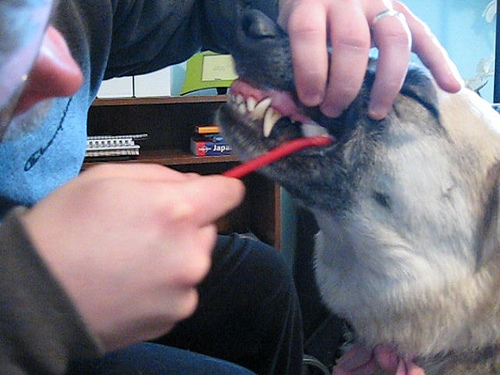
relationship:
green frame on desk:
[177, 48, 238, 100] [78, 85, 287, 262]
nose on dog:
[237, 6, 282, 41] [215, 6, 497, 373]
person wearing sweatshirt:
[1, 2, 463, 372] [0, 1, 275, 371]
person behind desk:
[1, 2, 465, 375] [77, 86, 292, 245]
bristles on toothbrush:
[301, 123, 327, 138] [217, 121, 330, 178]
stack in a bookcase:
[189, 124, 234, 154] [87, 94, 283, 252]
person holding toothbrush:
[1, 2, 465, 375] [210, 117, 339, 186]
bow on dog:
[333, 340, 425, 375] [206, 47, 496, 372]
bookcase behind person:
[81, 94, 283, 252] [1, 2, 463, 372]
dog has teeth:
[215, 6, 497, 373] [217, 88, 282, 140]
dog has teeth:
[215, 6, 499, 375] [236, 92, 328, 144]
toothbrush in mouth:
[217, 121, 335, 178] [217, 15, 342, 186]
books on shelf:
[186, 122, 238, 157] [81, 103, 231, 163]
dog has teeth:
[215, 6, 497, 373] [224, 82, 292, 135]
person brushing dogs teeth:
[1, 2, 463, 372] [211, 63, 303, 140]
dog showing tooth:
[215, 6, 497, 373] [262, 105, 282, 137]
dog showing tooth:
[215, 6, 497, 373] [245, 96, 257, 112]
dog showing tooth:
[215, 6, 497, 373] [235, 101, 247, 115]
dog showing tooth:
[215, 6, 497, 373] [235, 92, 243, 105]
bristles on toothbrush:
[301, 123, 327, 138] [220, 119, 336, 176]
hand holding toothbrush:
[30, 157, 246, 346] [269, 132, 329, 174]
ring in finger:
[370, 9, 405, 32] [377, 20, 407, 128]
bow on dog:
[333, 340, 425, 373] [215, 6, 497, 373]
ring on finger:
[368, 9, 406, 39] [364, 5, 411, 121]